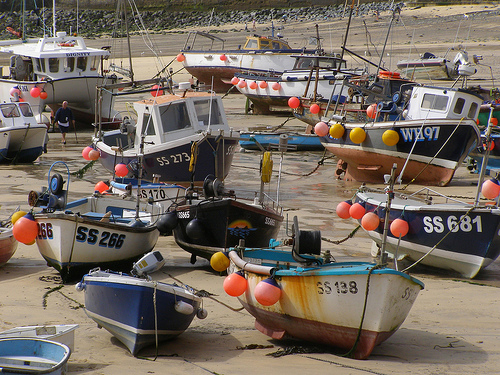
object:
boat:
[76, 268, 202, 355]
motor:
[130, 251, 166, 276]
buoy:
[254, 278, 281, 306]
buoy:
[210, 251, 230, 271]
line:
[45, 287, 84, 308]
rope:
[231, 155, 337, 176]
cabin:
[405, 85, 484, 122]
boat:
[319, 121, 480, 186]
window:
[421, 93, 448, 112]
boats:
[0, 32, 500, 375]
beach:
[0, 0, 500, 375]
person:
[54, 101, 75, 144]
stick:
[73, 121, 78, 143]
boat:
[227, 248, 425, 359]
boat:
[354, 186, 500, 280]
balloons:
[337, 200, 409, 238]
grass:
[0, 1, 399, 40]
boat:
[32, 199, 160, 283]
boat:
[92, 96, 236, 187]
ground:
[0, 0, 500, 375]